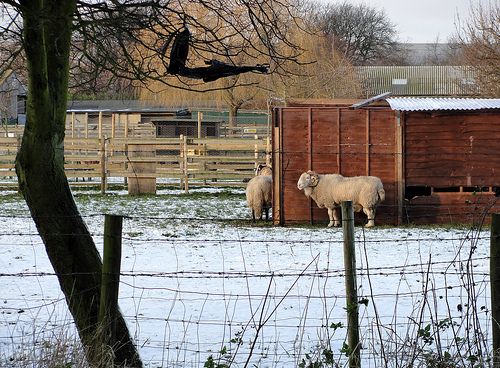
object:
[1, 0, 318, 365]
tree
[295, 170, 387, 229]
sheep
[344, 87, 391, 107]
plank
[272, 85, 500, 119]
roof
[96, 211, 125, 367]
post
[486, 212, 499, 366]
post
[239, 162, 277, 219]
sheep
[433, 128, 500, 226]
wall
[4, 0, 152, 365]
tree trunk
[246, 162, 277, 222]
lamb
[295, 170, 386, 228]
ram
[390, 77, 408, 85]
window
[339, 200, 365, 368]
fence pole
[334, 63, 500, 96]
metal building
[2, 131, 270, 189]
fence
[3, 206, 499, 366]
fence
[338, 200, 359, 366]
post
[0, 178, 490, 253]
grass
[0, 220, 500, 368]
snow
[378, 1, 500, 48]
sky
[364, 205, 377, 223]
leg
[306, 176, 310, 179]
eye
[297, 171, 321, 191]
head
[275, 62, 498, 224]
building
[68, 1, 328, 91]
branch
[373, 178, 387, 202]
tail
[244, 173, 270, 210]
body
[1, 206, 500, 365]
ground